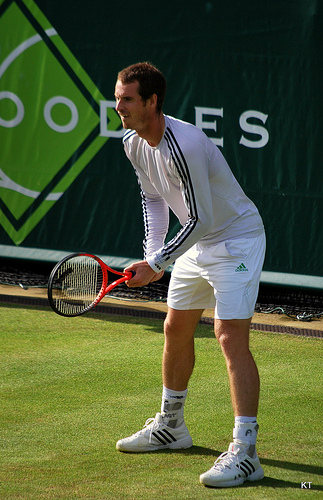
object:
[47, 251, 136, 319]
tennis racket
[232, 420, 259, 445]
splints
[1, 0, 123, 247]
logo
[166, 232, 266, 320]
tennis shorts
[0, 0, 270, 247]
sign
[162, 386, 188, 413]
sock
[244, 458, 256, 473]
stripes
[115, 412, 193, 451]
shoes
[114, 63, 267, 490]
player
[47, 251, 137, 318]
racket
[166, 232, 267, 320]
shorts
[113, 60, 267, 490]
man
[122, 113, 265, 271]
white shirt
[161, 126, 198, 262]
black stripes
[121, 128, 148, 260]
black stripes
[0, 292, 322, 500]
tennis court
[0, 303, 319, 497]
tenniscourt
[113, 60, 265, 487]
tennis player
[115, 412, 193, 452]
tennis shoes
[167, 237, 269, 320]
logo shorts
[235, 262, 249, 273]
logo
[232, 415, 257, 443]
sock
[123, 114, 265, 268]
shirt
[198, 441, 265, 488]
shoe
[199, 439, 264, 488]
tennis shoes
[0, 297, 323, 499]
grass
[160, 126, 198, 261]
stripes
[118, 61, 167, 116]
hair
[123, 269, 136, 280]
handle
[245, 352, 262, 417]
calf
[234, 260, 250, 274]
symbol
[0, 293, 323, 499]
court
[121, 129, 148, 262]
stripes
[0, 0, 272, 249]
sponsorship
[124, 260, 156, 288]
hands